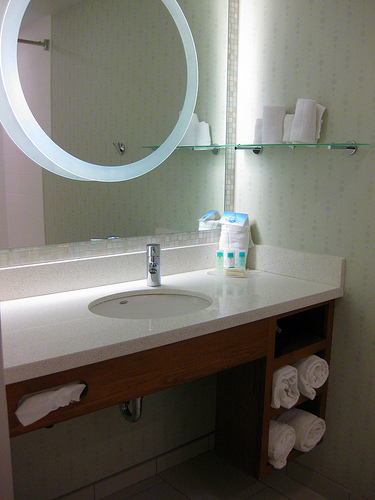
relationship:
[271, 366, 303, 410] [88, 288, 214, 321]
towel underneath sink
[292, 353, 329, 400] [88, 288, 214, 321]
towel underneath sink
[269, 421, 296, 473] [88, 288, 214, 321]
towel underneath sink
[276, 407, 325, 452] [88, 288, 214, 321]
towel underneath sink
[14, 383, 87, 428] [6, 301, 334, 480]
tissue inside cabinet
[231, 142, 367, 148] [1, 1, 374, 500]
shelf inside bathroom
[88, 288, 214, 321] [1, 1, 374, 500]
sink inside bathroom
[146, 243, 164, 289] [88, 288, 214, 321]
faucet above sink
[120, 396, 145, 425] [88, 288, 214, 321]
pipe underneath sink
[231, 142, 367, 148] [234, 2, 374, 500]
shelf hanging on wall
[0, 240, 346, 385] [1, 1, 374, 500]
counter inside bathroom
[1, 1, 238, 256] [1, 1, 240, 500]
mirror hanging on wall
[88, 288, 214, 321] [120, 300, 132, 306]
sink has hole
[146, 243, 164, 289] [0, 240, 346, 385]
faucet mounted on counter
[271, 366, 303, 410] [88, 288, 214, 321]
towel under sink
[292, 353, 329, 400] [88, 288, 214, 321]
towel under sink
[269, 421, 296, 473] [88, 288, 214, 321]
towel under sink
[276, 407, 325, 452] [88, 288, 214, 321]
towel under sink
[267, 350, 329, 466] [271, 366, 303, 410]
compartment holds towel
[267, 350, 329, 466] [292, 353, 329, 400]
compartment holds towel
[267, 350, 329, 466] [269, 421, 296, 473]
compartment holds towel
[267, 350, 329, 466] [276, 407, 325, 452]
compartment holds towel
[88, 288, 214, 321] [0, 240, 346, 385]
sink on top of counter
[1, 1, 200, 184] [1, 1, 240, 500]
mirror hanging on wall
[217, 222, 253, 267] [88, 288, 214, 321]
towel next to sink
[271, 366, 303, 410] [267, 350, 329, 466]
towel inside compartment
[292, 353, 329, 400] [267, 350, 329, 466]
towel inside compartment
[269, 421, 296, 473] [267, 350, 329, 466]
towel inside compartment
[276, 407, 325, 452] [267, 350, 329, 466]
towel inside compartment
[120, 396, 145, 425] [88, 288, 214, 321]
pipe under sink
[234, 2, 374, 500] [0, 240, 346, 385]
wall next to counter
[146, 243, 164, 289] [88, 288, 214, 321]
faucet over sink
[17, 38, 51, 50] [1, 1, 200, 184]
shower curtain rod reflected in mirror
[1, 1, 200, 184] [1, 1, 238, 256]
mirror on top of mirror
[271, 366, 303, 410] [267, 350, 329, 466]
towel rolled up inside compartment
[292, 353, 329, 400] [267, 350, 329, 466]
towel rolled up inside compartment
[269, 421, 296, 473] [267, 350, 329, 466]
towel rolled up inside compartment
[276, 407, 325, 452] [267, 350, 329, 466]
towel rolled up inside compartment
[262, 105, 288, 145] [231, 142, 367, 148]
hand towel sitting on shelf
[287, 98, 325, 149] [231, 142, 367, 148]
hand towel sitting on shelf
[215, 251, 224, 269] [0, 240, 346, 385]
shampoo sitting on counter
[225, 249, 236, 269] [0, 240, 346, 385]
conditioner sitting on counter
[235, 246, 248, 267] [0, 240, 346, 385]
lotion sitting on counter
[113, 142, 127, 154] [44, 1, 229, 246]
hook mounted on wall